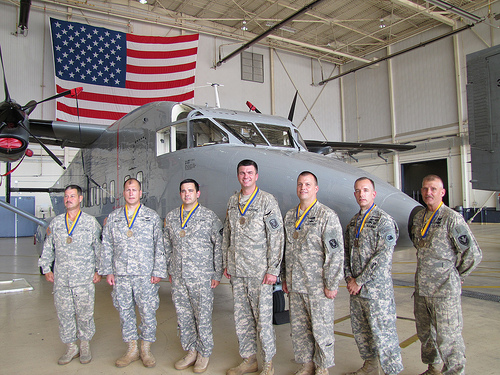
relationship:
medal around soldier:
[152, 179, 200, 223] [154, 163, 220, 316]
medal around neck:
[152, 179, 200, 223] [174, 201, 210, 218]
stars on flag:
[62, 3, 114, 64] [59, 19, 208, 133]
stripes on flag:
[115, 52, 246, 145] [59, 19, 208, 133]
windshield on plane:
[221, 125, 297, 147] [154, 101, 368, 206]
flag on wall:
[59, 19, 208, 133] [27, 12, 281, 120]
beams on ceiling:
[325, 5, 393, 58] [161, 11, 463, 119]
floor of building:
[11, 303, 53, 357] [43, 41, 472, 371]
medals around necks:
[123, 206, 266, 228] [63, 198, 277, 207]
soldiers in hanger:
[54, 149, 409, 304] [56, 30, 496, 371]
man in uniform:
[209, 129, 306, 335] [221, 207, 282, 276]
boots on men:
[117, 332, 168, 374] [68, 188, 479, 341]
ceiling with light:
[161, 11, 463, 119] [235, 20, 298, 50]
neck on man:
[174, 201, 210, 218] [209, 129, 306, 335]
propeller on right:
[13, 114, 61, 184] [42, 104, 166, 188]